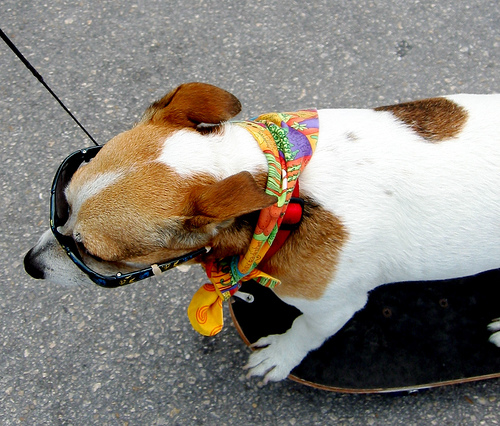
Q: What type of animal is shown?
A: Dog.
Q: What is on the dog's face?
A: Glasses.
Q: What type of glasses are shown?
A: Sunglasses.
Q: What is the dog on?
A: Skateboard.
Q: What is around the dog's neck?
A: Bandana.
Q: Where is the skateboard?
A: On the sidewalk.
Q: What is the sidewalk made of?
A: Concrete.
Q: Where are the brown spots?
A: On the dog.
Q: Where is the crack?
A: Sidewalk.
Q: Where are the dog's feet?
A: Skateboard.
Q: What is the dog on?
A: A skateboard.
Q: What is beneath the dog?
A: Speckled pavement.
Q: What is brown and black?
A: The skateboard.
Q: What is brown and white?
A: The dog.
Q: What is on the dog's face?
A: Black sunglasses.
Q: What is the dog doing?
A: Riding a skateboard.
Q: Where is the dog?
A: On a city sidewalk.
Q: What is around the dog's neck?
A: A colorful scarf.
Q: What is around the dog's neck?
A: A red collar.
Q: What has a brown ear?
A: The dog.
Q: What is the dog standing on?
A: Skateboard.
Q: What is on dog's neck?
A: Bandana.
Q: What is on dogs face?
A: Sunglasses.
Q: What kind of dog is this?
A: Jack Russell.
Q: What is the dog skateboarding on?
A: Concrete.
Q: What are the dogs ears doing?
A: Laying back.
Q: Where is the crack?
A: In the sidewalk.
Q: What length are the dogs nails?
A: Long.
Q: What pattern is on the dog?
A: Spot.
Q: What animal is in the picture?
A: A dog.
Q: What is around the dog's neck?
A: A bandana.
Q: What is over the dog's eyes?
A: Sunglasses.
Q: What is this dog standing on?
A: Skateboard.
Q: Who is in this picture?
A: No one.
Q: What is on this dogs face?
A: Sunglasses.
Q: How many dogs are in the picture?
A: One.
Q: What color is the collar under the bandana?
A: Red.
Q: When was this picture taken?
A: Daytime.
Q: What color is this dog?
A: Brown and white.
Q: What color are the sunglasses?
A: Black.